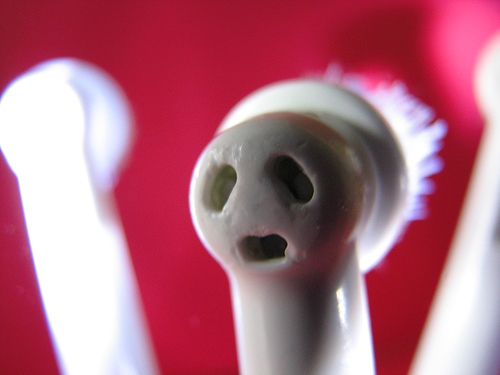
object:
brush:
[0, 55, 169, 375]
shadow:
[265, 270, 364, 375]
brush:
[185, 60, 448, 375]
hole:
[260, 148, 319, 209]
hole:
[233, 232, 292, 268]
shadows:
[327, 0, 449, 74]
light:
[375, 104, 431, 176]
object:
[399, 30, 499, 374]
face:
[185, 118, 345, 276]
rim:
[212, 74, 413, 277]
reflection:
[333, 285, 350, 332]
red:
[0, 0, 500, 375]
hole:
[200, 159, 239, 216]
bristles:
[288, 61, 449, 272]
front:
[211, 75, 413, 276]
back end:
[184, 114, 376, 281]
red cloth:
[2, 0, 499, 375]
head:
[186, 59, 450, 288]